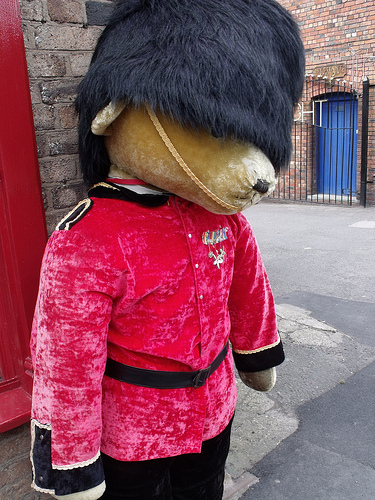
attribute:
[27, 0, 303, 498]
guard — royal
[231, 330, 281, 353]
trim — gold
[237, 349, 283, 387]
paws — brown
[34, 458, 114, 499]
paws — brown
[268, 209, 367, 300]
street — paved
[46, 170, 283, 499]
cuff — jacket's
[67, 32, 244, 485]
teddy bear — life sized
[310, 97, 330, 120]
ground — of pole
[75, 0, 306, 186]
hat — black, fur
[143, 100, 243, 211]
strap — chin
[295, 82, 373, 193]
fence — black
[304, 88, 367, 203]
door — blue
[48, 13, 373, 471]
bear — teddy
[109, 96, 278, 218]
face — dog's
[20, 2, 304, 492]
statue — brown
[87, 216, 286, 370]
cuff — coat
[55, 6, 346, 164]
hood — black, hairy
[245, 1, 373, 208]
wall — brick, house's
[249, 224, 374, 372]
pavement — mixed, stone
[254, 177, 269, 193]
nose — brown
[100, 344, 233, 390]
belt — black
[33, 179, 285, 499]
jacket — red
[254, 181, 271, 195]
nose — brown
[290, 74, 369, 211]
gate — metalic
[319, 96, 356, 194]
door — blue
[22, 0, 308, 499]
bear — teddy